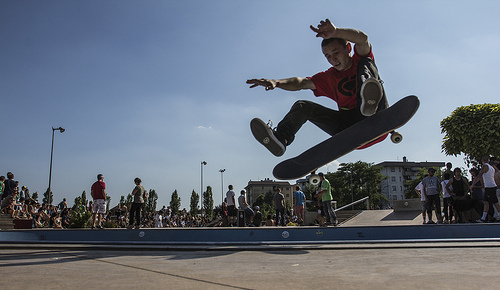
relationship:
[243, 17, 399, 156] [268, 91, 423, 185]
man doing trick on skateboard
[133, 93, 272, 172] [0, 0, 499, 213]
clouds in sky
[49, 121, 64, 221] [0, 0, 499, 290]
streetlight behind park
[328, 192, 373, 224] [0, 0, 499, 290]
railing at park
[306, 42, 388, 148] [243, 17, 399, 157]
red tshirt on man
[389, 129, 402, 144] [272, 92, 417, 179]
wheel on a skateboard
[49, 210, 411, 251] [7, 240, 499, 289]
rim around concrete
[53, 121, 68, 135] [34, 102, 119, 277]
light on a pole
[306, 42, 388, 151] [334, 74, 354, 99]
red tshirt with symbol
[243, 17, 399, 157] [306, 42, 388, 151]
man wearing red tshirt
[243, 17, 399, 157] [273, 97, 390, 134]
man wearing jeans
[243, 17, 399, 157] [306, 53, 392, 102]
man wearing shirt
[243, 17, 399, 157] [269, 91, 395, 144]
man wearing jeans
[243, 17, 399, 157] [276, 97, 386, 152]
man wearing jeans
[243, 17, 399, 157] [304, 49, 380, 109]
man wearing shirt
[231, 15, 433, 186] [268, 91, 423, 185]
guy on skateboard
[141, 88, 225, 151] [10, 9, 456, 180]
cloud in sky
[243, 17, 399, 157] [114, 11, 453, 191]
man in air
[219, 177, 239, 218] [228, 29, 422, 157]
back to skateboarder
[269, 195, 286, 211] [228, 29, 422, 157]
back to skateboarder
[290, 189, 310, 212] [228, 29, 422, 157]
back to skateboarder